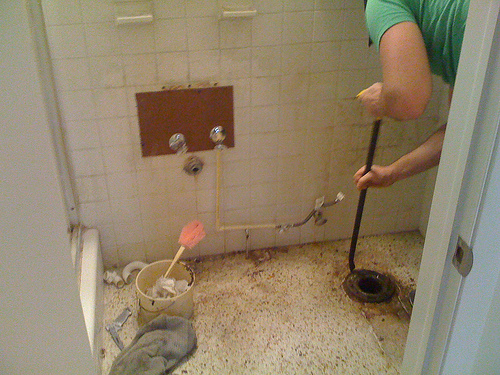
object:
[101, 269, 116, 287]
pipes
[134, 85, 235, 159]
square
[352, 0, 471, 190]
man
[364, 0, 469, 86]
shirt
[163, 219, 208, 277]
pink brush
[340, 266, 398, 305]
drain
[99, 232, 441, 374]
floor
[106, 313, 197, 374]
towel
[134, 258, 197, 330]
bucket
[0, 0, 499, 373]
room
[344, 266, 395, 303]
hole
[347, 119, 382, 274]
metal pole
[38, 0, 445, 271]
wall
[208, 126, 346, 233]
pipe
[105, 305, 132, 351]
knife